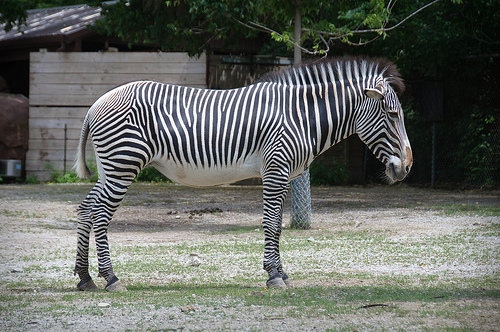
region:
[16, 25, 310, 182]
white building in the distance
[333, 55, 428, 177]
zebra's black and white head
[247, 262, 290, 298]
zebra's right front foot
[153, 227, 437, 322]
grassy area next to zebra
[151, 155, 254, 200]
azebra's white belly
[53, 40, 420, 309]
a zebra standing in open area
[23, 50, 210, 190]
a wooden building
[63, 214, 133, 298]
the back feet of a zebra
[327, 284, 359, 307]
this is the grass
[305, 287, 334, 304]
the grass is green in color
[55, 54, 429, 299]
this is a zebra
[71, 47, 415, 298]
the zebra is standing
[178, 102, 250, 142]
the fur is black and white in color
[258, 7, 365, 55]
this is a tree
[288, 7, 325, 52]
the tree is short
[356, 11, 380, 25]
the leaves are green in color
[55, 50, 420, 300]
A zebra in captivity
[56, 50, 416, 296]
A zebra in captivity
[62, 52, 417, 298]
A zebra in captivity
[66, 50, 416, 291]
A zebra in captivity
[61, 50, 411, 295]
A zebra in captivity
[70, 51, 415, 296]
A zebra in captivity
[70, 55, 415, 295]
A zebra in captivity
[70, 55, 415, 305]
A zebra in captivity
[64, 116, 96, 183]
Trimmed tail on zebra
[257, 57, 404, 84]
Mane of hair on zebra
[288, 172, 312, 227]
Wire mesh around tree trunk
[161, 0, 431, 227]
Leaf covered tree in enclosure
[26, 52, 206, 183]
Wooden plank wall in enclosure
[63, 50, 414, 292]
Zebra standing in profile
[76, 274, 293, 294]
Hooves on a zebra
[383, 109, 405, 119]
Black eye of zebra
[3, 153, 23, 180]
Air conditioning unit for building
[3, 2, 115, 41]
Slanted roof of building in background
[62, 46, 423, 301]
A zebra in captivity